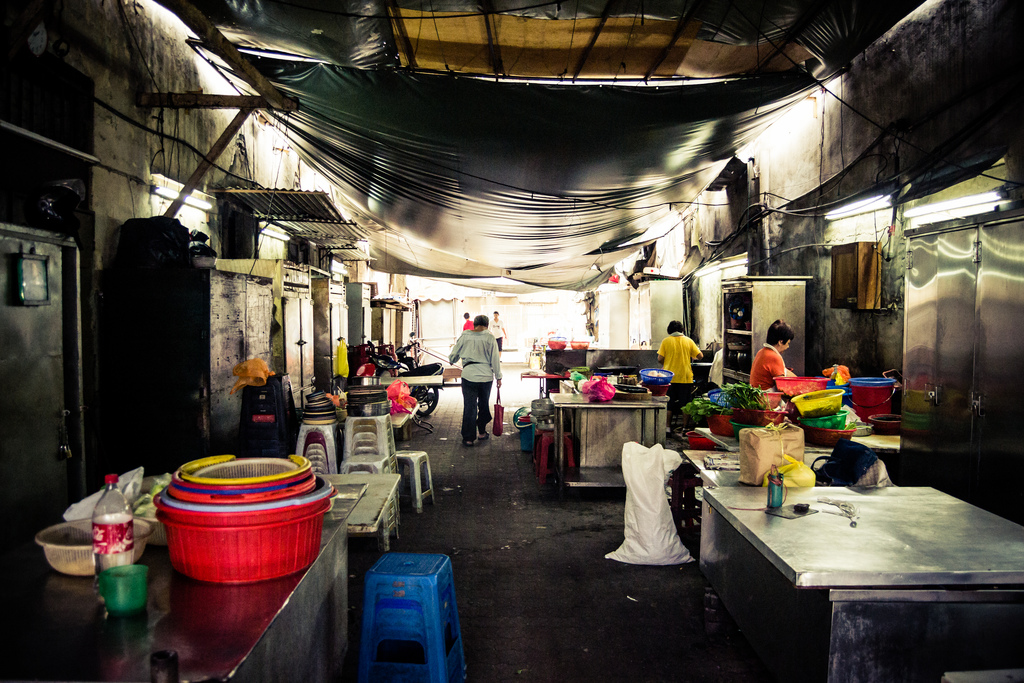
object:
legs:
[462, 378, 479, 444]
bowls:
[180, 454, 312, 486]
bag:
[602, 440, 695, 565]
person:
[447, 315, 504, 447]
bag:
[492, 385, 505, 436]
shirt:
[447, 328, 505, 382]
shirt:
[748, 347, 784, 391]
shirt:
[657, 332, 703, 383]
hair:
[666, 320, 683, 334]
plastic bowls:
[153, 452, 337, 585]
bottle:
[91, 474, 135, 604]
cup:
[99, 564, 148, 614]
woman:
[751, 319, 797, 394]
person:
[657, 320, 704, 437]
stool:
[362, 551, 471, 683]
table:
[0, 482, 380, 683]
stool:
[392, 450, 436, 513]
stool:
[339, 453, 393, 474]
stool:
[295, 421, 341, 474]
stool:
[343, 412, 400, 474]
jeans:
[462, 376, 495, 446]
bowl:
[772, 376, 830, 396]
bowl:
[789, 389, 844, 418]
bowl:
[849, 377, 896, 388]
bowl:
[755, 392, 785, 410]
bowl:
[797, 410, 851, 430]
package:
[737, 416, 805, 485]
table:
[682, 449, 840, 488]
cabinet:
[830, 241, 884, 309]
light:
[822, 194, 891, 220]